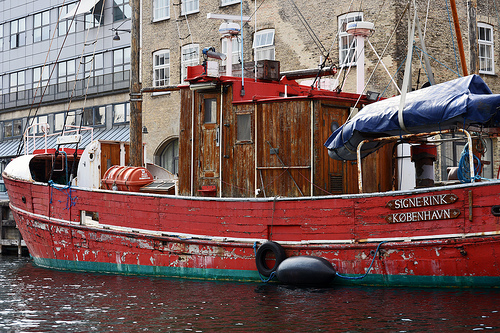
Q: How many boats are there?
A: One.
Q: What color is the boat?
A: Red.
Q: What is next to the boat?
A: A building.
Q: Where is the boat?
A: In the water.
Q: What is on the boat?
A: A little building.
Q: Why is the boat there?
A: To travel on the water.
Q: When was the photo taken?
A: During the day.